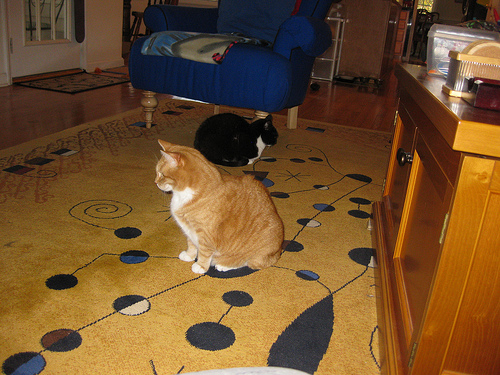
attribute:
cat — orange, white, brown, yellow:
[156, 136, 286, 276]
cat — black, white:
[193, 112, 278, 164]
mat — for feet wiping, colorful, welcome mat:
[17, 71, 127, 95]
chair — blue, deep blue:
[129, 0, 331, 130]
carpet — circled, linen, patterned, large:
[0, 101, 392, 373]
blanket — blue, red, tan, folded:
[142, 32, 255, 65]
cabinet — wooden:
[372, 63, 499, 373]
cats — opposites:
[153, 112, 284, 276]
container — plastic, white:
[426, 24, 499, 74]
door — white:
[5, 0, 82, 80]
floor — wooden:
[0, 68, 394, 164]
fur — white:
[170, 187, 200, 252]